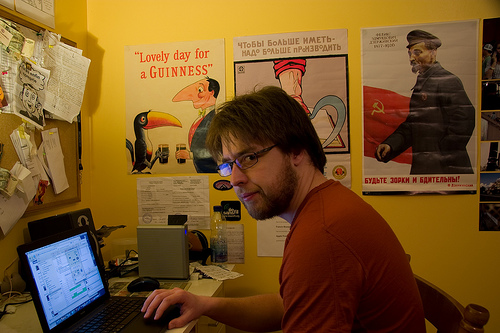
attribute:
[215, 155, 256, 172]
eyeglasses — pair, paired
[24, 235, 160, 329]
laptop — black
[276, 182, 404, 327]
shirt — orange, red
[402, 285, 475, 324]
chair — wooden, wood, brown, back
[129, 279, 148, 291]
mouse — black, dark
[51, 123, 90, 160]
cork board — peg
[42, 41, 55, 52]
pin — yellow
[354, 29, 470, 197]
poster — colorful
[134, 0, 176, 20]
wall — yellow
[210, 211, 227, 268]
bottle — empty, clear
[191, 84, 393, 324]
man — sitting, working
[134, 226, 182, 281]
modem — gray